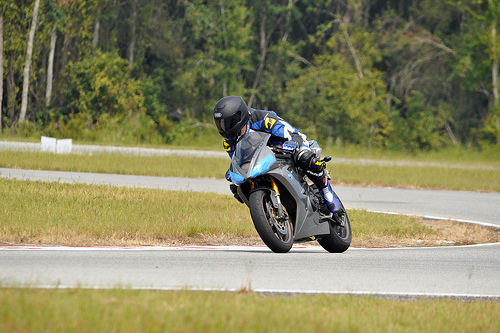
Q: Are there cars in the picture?
A: No, there are no cars.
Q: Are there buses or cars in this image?
A: No, there are no cars or buses.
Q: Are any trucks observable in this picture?
A: No, there are no trucks.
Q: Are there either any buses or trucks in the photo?
A: No, there are no trucks or buses.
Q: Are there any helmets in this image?
A: Yes, there is a helmet.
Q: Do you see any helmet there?
A: Yes, there is a helmet.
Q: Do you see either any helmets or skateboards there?
A: Yes, there is a helmet.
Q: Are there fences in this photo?
A: No, there are no fences.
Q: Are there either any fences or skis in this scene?
A: No, there are no fences or skis.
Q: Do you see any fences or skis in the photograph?
A: No, there are no fences or skis.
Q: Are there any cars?
A: No, there are no cars.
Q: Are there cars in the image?
A: No, there are no cars.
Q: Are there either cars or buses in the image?
A: No, there are no cars or buses.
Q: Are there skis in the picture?
A: No, there are no skis.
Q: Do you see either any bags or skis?
A: No, there are no skis or bags.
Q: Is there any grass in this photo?
A: Yes, there is grass.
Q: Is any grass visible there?
A: Yes, there is grass.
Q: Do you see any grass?
A: Yes, there is grass.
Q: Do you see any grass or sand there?
A: Yes, there is grass.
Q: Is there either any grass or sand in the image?
A: Yes, there is grass.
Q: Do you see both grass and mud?
A: No, there is grass but no mud.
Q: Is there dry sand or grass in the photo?
A: Yes, there is dry grass.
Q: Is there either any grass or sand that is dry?
A: Yes, the grass is dry.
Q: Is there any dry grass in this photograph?
A: Yes, there is dry grass.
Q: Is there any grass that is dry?
A: Yes, there is dry grass.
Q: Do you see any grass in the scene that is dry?
A: Yes, there is grass that is dry.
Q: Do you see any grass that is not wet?
A: Yes, there is dry grass.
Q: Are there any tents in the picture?
A: No, there are no tents.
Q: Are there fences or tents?
A: No, there are no tents or fences.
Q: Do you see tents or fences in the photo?
A: No, there are no tents or fences.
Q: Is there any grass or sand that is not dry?
A: No, there is grass but it is dry.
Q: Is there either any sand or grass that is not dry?
A: No, there is grass but it is dry.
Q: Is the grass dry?
A: Yes, the grass is dry.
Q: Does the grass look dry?
A: Yes, the grass is dry.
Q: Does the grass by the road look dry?
A: Yes, the grass is dry.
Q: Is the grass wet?
A: No, the grass is dry.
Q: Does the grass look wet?
A: No, the grass is dry.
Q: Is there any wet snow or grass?
A: No, there is grass but it is dry.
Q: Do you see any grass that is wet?
A: No, there is grass but it is dry.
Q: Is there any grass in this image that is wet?
A: No, there is grass but it is dry.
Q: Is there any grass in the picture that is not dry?
A: No, there is grass but it is dry.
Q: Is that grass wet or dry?
A: The grass is dry.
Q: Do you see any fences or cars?
A: No, there are no cars or fences.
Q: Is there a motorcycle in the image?
A: Yes, there is a motorcycle.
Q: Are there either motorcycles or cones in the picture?
A: Yes, there is a motorcycle.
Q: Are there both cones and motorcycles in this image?
A: No, there is a motorcycle but no cones.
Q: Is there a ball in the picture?
A: No, there are no balls.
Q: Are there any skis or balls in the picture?
A: No, there are no balls or skis.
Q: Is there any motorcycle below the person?
A: Yes, there is a motorcycle below the person.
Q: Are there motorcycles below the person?
A: Yes, there is a motorcycle below the person.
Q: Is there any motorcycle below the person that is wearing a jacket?
A: Yes, there is a motorcycle below the person.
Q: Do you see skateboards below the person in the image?
A: No, there is a motorcycle below the person.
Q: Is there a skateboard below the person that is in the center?
A: No, there is a motorcycle below the person.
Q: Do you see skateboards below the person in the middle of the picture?
A: No, there is a motorcycle below the person.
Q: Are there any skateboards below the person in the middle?
A: No, there is a motorcycle below the person.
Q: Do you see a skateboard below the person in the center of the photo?
A: No, there is a motorcycle below the person.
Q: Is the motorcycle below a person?
A: Yes, the motorcycle is below a person.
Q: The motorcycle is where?
A: The motorcycle is on the road.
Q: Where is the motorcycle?
A: The motorcycle is on the road.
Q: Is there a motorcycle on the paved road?
A: Yes, there is a motorcycle on the road.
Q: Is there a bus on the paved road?
A: No, there is a motorcycle on the road.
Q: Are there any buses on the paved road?
A: No, there is a motorcycle on the road.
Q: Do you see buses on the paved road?
A: No, there is a motorcycle on the road.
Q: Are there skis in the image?
A: No, there are no skis.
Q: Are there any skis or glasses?
A: No, there are no skis or glasses.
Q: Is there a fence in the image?
A: No, there are no fences.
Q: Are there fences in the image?
A: No, there are no fences.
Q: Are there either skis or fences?
A: No, there are no fences or skis.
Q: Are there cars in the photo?
A: No, there are no cars.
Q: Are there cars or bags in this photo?
A: No, there are no cars or bags.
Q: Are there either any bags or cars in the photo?
A: No, there are no cars or bags.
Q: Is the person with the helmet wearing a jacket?
A: Yes, the person is wearing a jacket.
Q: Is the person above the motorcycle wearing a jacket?
A: Yes, the person is wearing a jacket.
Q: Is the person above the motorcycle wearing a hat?
A: No, the person is wearing a jacket.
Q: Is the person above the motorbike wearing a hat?
A: No, the person is wearing a jacket.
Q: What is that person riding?
A: The person is riding a motorcycle.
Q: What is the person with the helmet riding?
A: The person is riding a motorcycle.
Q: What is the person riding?
A: The person is riding a motorcycle.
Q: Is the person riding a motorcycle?
A: Yes, the person is riding a motorcycle.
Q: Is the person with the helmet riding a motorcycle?
A: Yes, the person is riding a motorcycle.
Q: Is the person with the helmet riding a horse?
A: No, the person is riding a motorcycle.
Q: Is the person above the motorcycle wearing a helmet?
A: Yes, the person is wearing a helmet.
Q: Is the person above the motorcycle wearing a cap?
A: No, the person is wearing a helmet.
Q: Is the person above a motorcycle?
A: Yes, the person is above a motorcycle.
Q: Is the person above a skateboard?
A: No, the person is above a motorcycle.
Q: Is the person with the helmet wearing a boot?
A: Yes, the person is wearing a boot.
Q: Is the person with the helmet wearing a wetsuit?
A: No, the person is wearing a boot.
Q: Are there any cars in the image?
A: No, there are no cars.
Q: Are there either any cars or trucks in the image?
A: No, there are no cars or trucks.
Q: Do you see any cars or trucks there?
A: No, there are no cars or trucks.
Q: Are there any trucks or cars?
A: No, there are no cars or trucks.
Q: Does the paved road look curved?
A: Yes, the road is curved.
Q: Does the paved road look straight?
A: No, the road is curved.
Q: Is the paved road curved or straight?
A: The road is curved.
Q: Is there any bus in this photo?
A: No, there are no buses.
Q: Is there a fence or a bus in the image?
A: No, there are no buses or fences.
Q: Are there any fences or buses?
A: No, there are no buses or fences.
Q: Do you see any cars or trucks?
A: No, there are no cars or trucks.